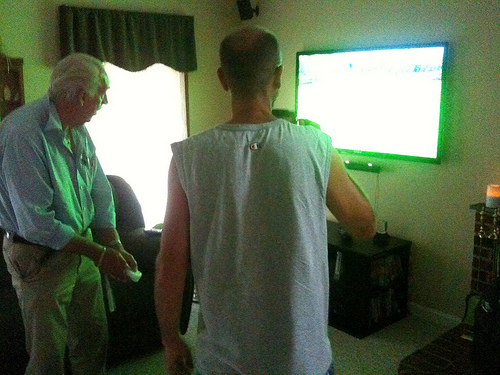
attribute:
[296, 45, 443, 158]
screen — bright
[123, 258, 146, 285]
controller — white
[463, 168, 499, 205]
candle — lit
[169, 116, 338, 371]
sleeveless shirt — gray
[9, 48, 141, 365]
man — old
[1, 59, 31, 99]
shelf — brown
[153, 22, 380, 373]
man — middle aged, balding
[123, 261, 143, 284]
remote — white